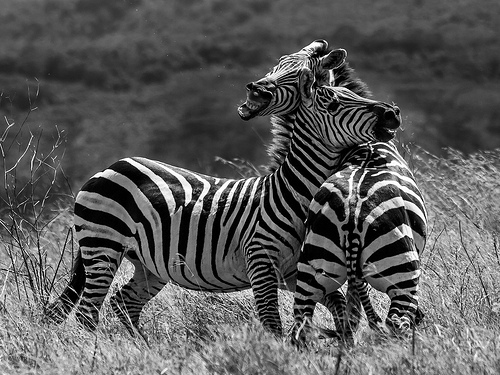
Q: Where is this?
A: This is at the field.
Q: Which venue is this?
A: This is a field.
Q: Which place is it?
A: It is a field.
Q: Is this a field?
A: Yes, it is a field.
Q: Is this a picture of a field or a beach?
A: It is showing a field.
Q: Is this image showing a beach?
A: No, the picture is showing a field.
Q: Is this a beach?
A: No, it is a field.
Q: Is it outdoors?
A: Yes, it is outdoors.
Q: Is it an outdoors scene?
A: Yes, it is outdoors.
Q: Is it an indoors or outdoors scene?
A: It is outdoors.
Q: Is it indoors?
A: No, it is outdoors.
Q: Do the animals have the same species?
A: Yes, all the animals are zebras.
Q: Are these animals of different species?
A: No, all the animals are zebras.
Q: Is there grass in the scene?
A: Yes, there is grass.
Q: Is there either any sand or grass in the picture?
A: Yes, there is grass.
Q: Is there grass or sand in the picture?
A: Yes, there is grass.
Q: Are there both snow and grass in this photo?
A: No, there is grass but no snow.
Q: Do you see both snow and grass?
A: No, there is grass but no snow.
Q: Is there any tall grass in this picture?
A: Yes, there is tall grass.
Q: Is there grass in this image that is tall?
A: Yes, there is tall grass.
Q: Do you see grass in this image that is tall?
A: Yes, there is grass that is tall.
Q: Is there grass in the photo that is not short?
A: Yes, there is tall grass.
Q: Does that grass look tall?
A: Yes, the grass is tall.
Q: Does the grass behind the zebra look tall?
A: Yes, the grass is tall.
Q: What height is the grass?
A: The grass is tall.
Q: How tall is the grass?
A: The grass is tall.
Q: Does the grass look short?
A: No, the grass is tall.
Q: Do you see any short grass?
A: No, there is grass but it is tall.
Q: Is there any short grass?
A: No, there is grass but it is tall.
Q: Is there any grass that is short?
A: No, there is grass but it is tall.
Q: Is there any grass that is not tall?
A: No, there is grass but it is tall.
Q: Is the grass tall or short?
A: The grass is tall.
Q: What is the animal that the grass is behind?
A: The animal is a zebra.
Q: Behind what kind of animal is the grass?
A: The grass is behind the zebra.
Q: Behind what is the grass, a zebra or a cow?
A: The grass is behind a zebra.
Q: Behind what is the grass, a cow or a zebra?
A: The grass is behind a zebra.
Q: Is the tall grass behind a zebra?
A: Yes, the grass is behind a zebra.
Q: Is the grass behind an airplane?
A: No, the grass is behind a zebra.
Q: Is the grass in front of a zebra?
A: No, the grass is behind a zebra.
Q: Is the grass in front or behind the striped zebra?
A: The grass is behind the zebra.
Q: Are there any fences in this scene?
A: No, there are no fences.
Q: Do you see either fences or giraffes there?
A: No, there are no fences or giraffes.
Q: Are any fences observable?
A: No, there are no fences.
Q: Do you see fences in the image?
A: No, there are no fences.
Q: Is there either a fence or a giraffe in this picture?
A: No, there are no fences or giraffes.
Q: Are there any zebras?
A: Yes, there is a zebra.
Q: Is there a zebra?
A: Yes, there is a zebra.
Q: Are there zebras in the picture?
A: Yes, there is a zebra.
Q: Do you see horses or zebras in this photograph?
A: Yes, there is a zebra.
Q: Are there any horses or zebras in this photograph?
A: Yes, there is a zebra.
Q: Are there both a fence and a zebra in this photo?
A: No, there is a zebra but no fences.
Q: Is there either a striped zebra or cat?
A: Yes, there is a striped zebra.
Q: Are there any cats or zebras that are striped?
A: Yes, the zebra is striped.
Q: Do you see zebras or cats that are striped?
A: Yes, the zebra is striped.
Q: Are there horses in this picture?
A: No, there are no horses.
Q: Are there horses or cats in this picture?
A: No, there are no horses or cats.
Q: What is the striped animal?
A: The animal is a zebra.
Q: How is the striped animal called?
A: The animal is a zebra.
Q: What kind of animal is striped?
A: The animal is a zebra.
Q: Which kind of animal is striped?
A: The animal is a zebra.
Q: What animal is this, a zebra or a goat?
A: This is a zebra.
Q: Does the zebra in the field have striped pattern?
A: Yes, the zebra is striped.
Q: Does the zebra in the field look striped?
A: Yes, the zebra is striped.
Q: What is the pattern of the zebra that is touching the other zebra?
A: The zebra is striped.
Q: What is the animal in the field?
A: The animal is a zebra.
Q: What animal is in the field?
A: The animal is a zebra.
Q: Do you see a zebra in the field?
A: Yes, there is a zebra in the field.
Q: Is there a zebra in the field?
A: Yes, there is a zebra in the field.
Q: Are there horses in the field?
A: No, there is a zebra in the field.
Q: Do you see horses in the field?
A: No, there is a zebra in the field.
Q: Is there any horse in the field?
A: No, there is a zebra in the field.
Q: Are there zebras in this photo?
A: Yes, there is a zebra.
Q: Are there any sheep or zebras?
A: Yes, there is a zebra.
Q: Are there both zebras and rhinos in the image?
A: No, there is a zebra but no rhinos.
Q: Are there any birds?
A: No, there are no birds.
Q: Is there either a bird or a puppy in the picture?
A: No, there are no birds or puppies.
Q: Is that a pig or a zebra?
A: That is a zebra.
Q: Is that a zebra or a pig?
A: That is a zebra.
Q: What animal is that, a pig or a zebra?
A: That is a zebra.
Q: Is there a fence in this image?
A: No, there are no fences.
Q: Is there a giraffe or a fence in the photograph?
A: No, there are no fences or giraffes.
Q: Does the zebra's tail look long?
A: Yes, the tail is long.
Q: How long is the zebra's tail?
A: The tail is long.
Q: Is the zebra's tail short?
A: No, the tail is long.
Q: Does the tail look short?
A: No, the tail is long.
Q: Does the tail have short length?
A: No, the tail is long.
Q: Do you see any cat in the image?
A: No, there are no cats.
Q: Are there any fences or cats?
A: No, there are no cats or fences.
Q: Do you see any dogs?
A: No, there are no dogs.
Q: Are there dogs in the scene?
A: No, there are no dogs.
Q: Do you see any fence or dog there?
A: No, there are no dogs or fences.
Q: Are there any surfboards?
A: No, there are no surfboards.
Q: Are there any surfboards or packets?
A: No, there are no surfboards or packets.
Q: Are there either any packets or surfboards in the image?
A: No, there are no surfboards or packets.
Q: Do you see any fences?
A: No, there are no fences.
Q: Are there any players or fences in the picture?
A: No, there are no fences or players.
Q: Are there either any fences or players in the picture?
A: No, there are no fences or players.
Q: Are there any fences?
A: No, there are no fences.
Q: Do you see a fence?
A: No, there are no fences.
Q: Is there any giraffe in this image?
A: No, there are no giraffes.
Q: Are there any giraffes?
A: No, there are no giraffes.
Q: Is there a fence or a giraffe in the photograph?
A: No, there are no giraffes or fences.